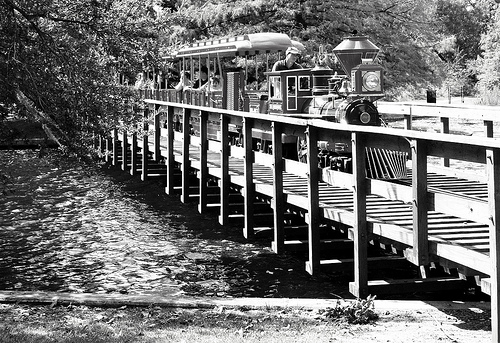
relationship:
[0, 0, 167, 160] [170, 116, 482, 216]
trees on track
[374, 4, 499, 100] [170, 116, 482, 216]
trees on track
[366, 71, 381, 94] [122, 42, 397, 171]
light on train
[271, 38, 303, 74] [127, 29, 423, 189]
guy on train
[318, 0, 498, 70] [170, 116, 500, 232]
trees around track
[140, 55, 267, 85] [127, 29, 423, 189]
people on a train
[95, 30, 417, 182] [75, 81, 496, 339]
train on bridge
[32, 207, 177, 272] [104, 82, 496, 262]
water under bridge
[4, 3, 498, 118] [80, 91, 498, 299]
trees under bridge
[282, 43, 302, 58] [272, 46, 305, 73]
hat on guy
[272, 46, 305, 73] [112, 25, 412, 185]
guy on train